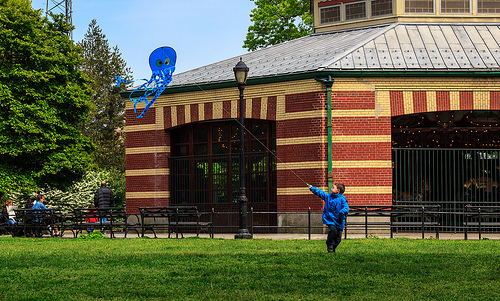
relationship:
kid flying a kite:
[303, 178, 351, 259] [110, 41, 182, 120]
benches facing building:
[9, 206, 215, 238] [112, 1, 494, 237]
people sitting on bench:
[2, 190, 52, 235] [8, 205, 60, 237]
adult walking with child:
[82, 177, 116, 237] [83, 202, 100, 234]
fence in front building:
[204, 208, 499, 244] [112, 1, 494, 237]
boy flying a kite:
[303, 178, 351, 259] [110, 41, 182, 120]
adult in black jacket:
[91, 180, 115, 224] [93, 184, 116, 217]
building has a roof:
[112, 1, 494, 237] [120, 2, 499, 93]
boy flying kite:
[303, 178, 351, 259] [110, 41, 182, 120]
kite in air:
[110, 41, 182, 120] [48, 8, 280, 135]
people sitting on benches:
[2, 190, 52, 235] [8, 205, 60, 237]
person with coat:
[82, 177, 116, 237] [93, 184, 116, 217]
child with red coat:
[83, 202, 100, 234] [82, 209, 99, 224]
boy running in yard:
[303, 178, 351, 259] [2, 237, 499, 301]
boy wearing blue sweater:
[303, 178, 351, 259] [307, 185, 354, 227]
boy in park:
[303, 178, 351, 259] [2, 237, 499, 301]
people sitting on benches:
[2, 190, 52, 235] [9, 206, 215, 238]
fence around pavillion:
[204, 208, 499, 244] [92, 9, 499, 258]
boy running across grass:
[303, 178, 351, 259] [2, 237, 499, 301]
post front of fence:
[231, 53, 254, 242] [204, 208, 499, 244]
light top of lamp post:
[232, 53, 252, 95] [231, 53, 254, 242]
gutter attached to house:
[281, 65, 495, 84] [112, 1, 494, 237]